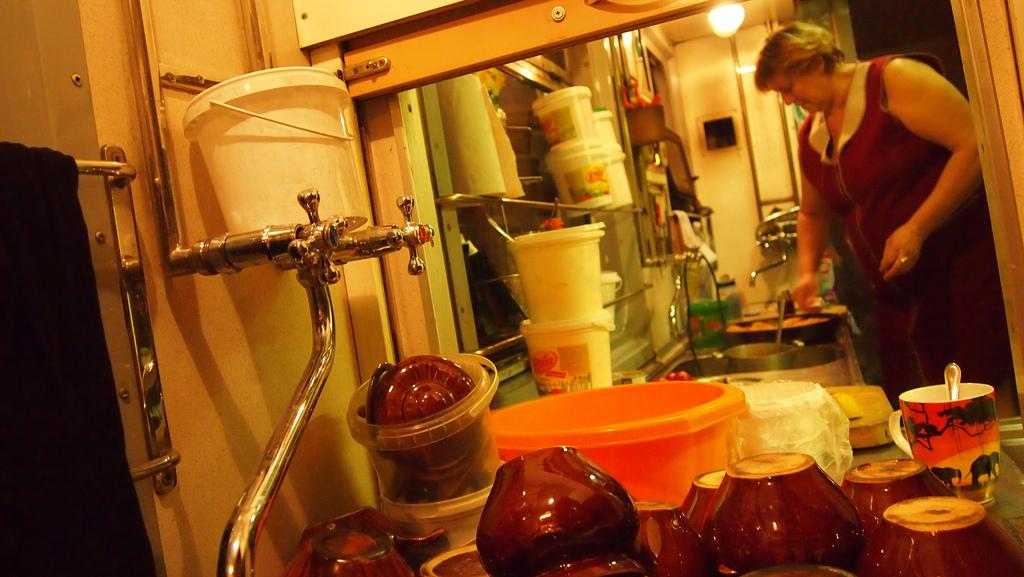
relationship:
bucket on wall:
[180, 63, 371, 239] [30, 15, 399, 525]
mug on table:
[882, 375, 1005, 512] [281, 354, 1021, 568]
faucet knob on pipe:
[273, 182, 439, 287] [209, 270, 344, 573]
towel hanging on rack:
[5, 132, 176, 569] [62, 146, 185, 488]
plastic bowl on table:
[479, 378, 752, 511] [285, 367, 1008, 574]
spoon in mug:
[939, 360, 979, 401] [881, 365, 1009, 503]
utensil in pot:
[769, 292, 800, 354] [723, 332, 843, 376]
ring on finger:
[896, 247, 915, 269] [887, 249, 909, 281]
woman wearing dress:
[756, 22, 1011, 429] [791, 63, 1018, 387]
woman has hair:
[756, 22, 1011, 429] [748, 19, 843, 80]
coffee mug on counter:
[885, 377, 1007, 502] [285, 327, 1022, 563]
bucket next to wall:
[170, 52, 377, 244] [30, 15, 399, 525]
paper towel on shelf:
[432, 63, 543, 245] [160, 152, 604, 325]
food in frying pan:
[700, 230, 860, 386] [689, 257, 849, 346]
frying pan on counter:
[689, 257, 849, 346] [527, 214, 837, 348]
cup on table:
[693, 448, 872, 576] [387, 318, 917, 543]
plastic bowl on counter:
[479, 378, 752, 511] [291, 302, 1023, 575]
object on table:
[464, 257, 622, 415] [371, 335, 983, 569]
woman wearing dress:
[756, 22, 1012, 429] [760, 102, 966, 401]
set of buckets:
[488, 130, 625, 403] [464, 96, 650, 412]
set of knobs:
[205, 156, 381, 295] [233, 162, 471, 286]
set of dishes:
[158, 158, 571, 347] [242, 219, 744, 509]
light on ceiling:
[689, 0, 767, 59] [136, 0, 804, 106]